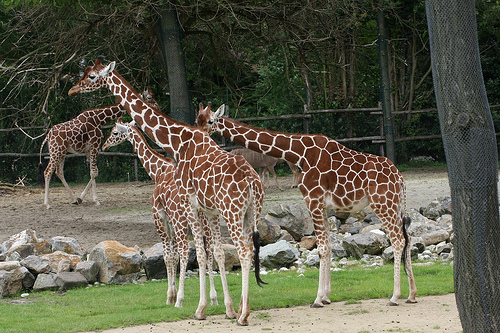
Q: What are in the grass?
A: Giraffe.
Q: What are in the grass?
A: Giraffe.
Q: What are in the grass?
A: Giraffe.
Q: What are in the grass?
A: Stoens.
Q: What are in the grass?
A: Trees.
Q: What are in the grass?
A: Giraffe.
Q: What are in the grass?
A: Giraffe.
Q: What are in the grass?
A: Trees.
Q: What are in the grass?
A: Rocks.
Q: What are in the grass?
A: Trees.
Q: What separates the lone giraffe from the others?
A: A rock wall.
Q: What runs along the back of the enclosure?
A: A fence.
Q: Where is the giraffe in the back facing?
A: Right.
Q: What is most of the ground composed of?
A: Dirt.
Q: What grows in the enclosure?
A: Grass.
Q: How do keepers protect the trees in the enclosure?
A: Wire around their trunks.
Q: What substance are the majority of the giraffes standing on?
A: Grass.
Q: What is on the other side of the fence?
A: Trees.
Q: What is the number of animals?
A: Four.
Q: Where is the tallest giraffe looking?
A: To the left.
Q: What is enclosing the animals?
A: A fence.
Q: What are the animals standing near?
A: Wall of stones.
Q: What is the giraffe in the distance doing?
A: Walking.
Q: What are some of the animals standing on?
A: Green grass.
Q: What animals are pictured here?
A: Giraffes.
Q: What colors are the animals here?
A: Brown and White.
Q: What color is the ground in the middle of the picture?
A: Green.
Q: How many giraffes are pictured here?
A: Four.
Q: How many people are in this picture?
A: Zero.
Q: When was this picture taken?
A: Daytime.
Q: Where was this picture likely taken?
A: A Zoo.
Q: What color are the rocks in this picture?
A: Grey and Brown.